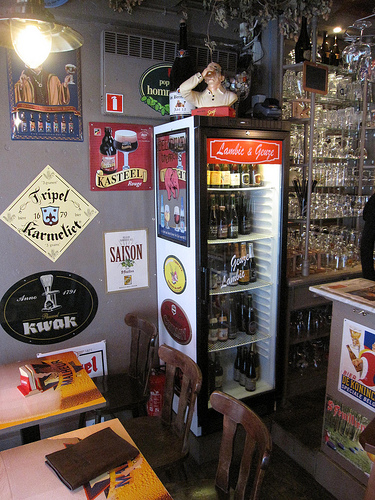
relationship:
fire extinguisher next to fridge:
[146, 363, 167, 413] [149, 113, 280, 438]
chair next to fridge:
[81, 299, 155, 419] [149, 113, 280, 438]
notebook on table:
[45, 426, 136, 492] [4, 415, 172, 498]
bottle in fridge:
[241, 295, 259, 335] [149, 113, 280, 438]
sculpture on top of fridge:
[175, 59, 241, 117] [149, 113, 280, 438]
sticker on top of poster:
[102, 93, 127, 114] [88, 123, 154, 191]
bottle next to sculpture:
[161, 18, 198, 115] [175, 59, 241, 117]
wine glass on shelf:
[332, 234, 347, 270] [290, 218, 365, 283]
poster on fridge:
[152, 127, 195, 249] [149, 113, 280, 438]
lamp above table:
[3, 3, 85, 74] [4, 415, 172, 498]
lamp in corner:
[3, 3, 85, 74] [1, 2, 106, 170]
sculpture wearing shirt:
[175, 59, 241, 117] [179, 73, 235, 107]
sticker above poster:
[102, 93, 127, 114] [88, 123, 154, 191]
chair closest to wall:
[81, 299, 155, 419] [5, 6, 277, 401]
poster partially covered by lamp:
[5, 40, 86, 143] [3, 3, 85, 74]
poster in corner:
[5, 40, 86, 143] [1, 2, 106, 170]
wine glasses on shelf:
[307, 229, 349, 271] [290, 218, 365, 283]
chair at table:
[185, 386, 284, 497] [4, 415, 172, 498]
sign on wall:
[0, 266, 105, 348] [5, 6, 277, 401]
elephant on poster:
[161, 166, 182, 204] [152, 127, 195, 249]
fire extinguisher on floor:
[146, 363, 167, 413] [9, 394, 372, 499]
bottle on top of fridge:
[161, 18, 198, 115] [149, 113, 280, 438]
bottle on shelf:
[241, 295, 259, 335] [208, 287, 268, 348]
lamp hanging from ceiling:
[3, 3, 85, 74] [3, 3, 374, 74]